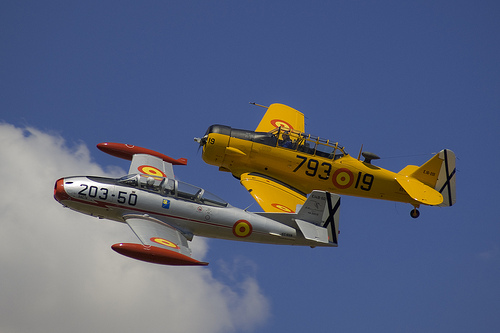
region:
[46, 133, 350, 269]
gray and red airplane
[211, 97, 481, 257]
yellow and red airplane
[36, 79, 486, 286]
planes flying closely together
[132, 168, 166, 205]
the pilot is in the cockpit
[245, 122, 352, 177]
the plane seats very few passangers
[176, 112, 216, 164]
the propeller spins rapidly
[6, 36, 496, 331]
the weather is sunny with a few clouds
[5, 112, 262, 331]
the clouds are fluffy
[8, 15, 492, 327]
low chance of rain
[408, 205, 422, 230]
landing gear remains down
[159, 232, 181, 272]
the circle is red and yellow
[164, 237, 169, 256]
the circle is red and yellow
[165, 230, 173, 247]
the circle is red and yellow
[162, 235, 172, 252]
the circle is red and yellow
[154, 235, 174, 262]
the circle is red and yellow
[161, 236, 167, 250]
the circle is red and yellow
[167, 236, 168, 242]
the circle is red and yellow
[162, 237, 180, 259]
the circle is red and yellow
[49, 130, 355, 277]
silver and red plane flying in sky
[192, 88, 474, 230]
yellow and black plane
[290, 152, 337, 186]
793 on side of plane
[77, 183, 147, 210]
203-50 on side of plane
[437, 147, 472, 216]
x on tail of plane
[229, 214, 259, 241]
yellow and red target on plane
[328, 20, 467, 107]
clear blue sky in background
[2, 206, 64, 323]
grey cloud in sky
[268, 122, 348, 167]
pilot on yellow plane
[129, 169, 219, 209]
pilot in silver plane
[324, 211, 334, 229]
the x spot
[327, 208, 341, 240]
the x spot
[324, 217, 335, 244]
the x spot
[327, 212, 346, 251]
the x spot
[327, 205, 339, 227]
the x spot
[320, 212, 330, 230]
the x spot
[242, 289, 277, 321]
the sky is blue and cloudy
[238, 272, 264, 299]
the sky is blue and cloudy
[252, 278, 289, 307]
the sky is blue and cloudy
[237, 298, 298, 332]
the sky is blue and cloudy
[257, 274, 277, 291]
the sky is blue and cloudy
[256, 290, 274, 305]
the sky is blue and cloudy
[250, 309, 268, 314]
the sky is blue and cloudy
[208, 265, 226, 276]
the sky is blue and cloudy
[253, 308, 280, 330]
the sky is blue and cloudy